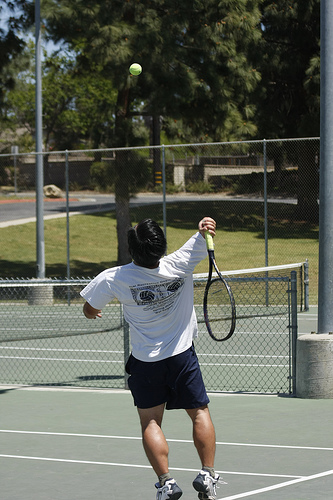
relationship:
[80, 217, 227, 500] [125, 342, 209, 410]
man wearing shorts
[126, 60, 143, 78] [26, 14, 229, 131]
ball in air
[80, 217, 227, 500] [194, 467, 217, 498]
man has tennis shoe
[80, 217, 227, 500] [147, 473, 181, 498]
man has tennis shoe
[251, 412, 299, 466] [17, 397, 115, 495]
line on court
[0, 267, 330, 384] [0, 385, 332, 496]
fence surrounds tennis court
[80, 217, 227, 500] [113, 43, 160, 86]
man hits ball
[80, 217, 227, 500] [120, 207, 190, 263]
man has head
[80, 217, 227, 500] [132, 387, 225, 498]
man has legs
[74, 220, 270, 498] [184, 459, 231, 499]
man has foot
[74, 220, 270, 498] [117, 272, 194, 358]
man has back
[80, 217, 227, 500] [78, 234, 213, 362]
man wears shirt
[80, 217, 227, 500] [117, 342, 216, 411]
man wears blue shorts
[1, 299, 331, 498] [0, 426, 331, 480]
court has lines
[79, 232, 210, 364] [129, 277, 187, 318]
shirt has image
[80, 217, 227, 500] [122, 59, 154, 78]
man readying to hit tennis ball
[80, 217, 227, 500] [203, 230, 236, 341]
man holding racket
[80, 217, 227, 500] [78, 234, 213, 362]
man wearing shirt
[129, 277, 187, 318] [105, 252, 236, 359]
image on shirt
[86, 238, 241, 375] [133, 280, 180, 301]
shirt printed with image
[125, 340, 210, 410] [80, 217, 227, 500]
blue shorts on man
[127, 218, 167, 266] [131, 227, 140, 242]
hair in hair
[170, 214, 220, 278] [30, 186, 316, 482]
arm on man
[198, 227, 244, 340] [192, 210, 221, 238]
racket in hand